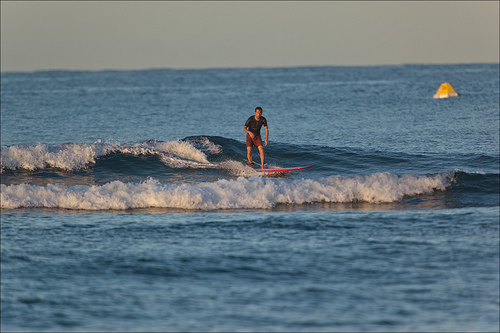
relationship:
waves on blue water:
[0, 135, 500, 174] [0, 63, 500, 331]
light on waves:
[177, 128, 367, 217] [203, 161, 474, 269]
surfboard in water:
[209, 141, 339, 197] [197, 197, 367, 284]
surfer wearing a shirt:
[241, 106, 268, 170] [248, 114, 267, 141]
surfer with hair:
[241, 106, 268, 170] [249, 102, 266, 117]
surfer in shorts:
[241, 106, 268, 170] [235, 131, 267, 171]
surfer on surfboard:
[241, 106, 268, 170] [230, 154, 282, 177]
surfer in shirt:
[241, 106, 268, 170] [246, 116, 270, 148]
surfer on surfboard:
[241, 106, 268, 170] [243, 152, 296, 177]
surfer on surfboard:
[241, 106, 268, 170] [239, 150, 270, 179]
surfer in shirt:
[241, 106, 268, 170] [241, 116, 273, 146]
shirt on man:
[246, 116, 268, 137] [241, 106, 268, 156]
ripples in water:
[0, 63, 500, 332] [7, 68, 497, 331]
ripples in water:
[175, 289, 306, 319] [7, 68, 497, 331]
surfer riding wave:
[241, 106, 268, 170] [0, 168, 500, 210]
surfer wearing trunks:
[241, 106, 268, 170] [244, 130, 261, 150]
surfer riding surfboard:
[241, 106, 268, 170] [233, 158, 313, 178]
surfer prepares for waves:
[241, 106, 268, 170] [9, 125, 489, 229]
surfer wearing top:
[241, 106, 268, 170] [241, 115, 271, 138]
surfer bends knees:
[241, 106, 268, 170] [239, 144, 268, 155]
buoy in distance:
[431, 66, 471, 106] [6, 57, 488, 148]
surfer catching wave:
[241, 106, 268, 170] [5, 127, 495, 230]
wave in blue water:
[0, 168, 500, 210] [0, 63, 500, 331]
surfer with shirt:
[234, 98, 284, 163] [243, 116, 266, 138]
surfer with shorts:
[241, 106, 268, 170] [238, 130, 273, 151]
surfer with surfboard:
[241, 106, 268, 170] [258, 163, 316, 174]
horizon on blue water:
[0, 62, 430, 102] [0, 63, 500, 331]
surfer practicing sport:
[241, 106, 268, 170] [241, 104, 308, 174]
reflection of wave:
[160, 174, 362, 211] [0, 168, 500, 210]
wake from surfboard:
[173, 155, 242, 175] [253, 163, 311, 174]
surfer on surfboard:
[241, 106, 268, 170] [258, 162, 314, 175]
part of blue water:
[334, 261, 414, 304] [16, 217, 482, 330]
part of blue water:
[64, 237, 128, 278] [16, 217, 482, 330]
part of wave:
[365, 171, 423, 203] [0, 168, 500, 210]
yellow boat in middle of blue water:
[430, 82, 456, 100] [0, 63, 500, 331]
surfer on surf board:
[241, 106, 268, 170] [256, 162, 316, 176]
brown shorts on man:
[245, 133, 261, 144] [242, 105, 268, 170]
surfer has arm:
[241, 106, 268, 170] [263, 121, 271, 147]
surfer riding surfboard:
[241, 106, 268, 170] [256, 161, 310, 174]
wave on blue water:
[0, 168, 500, 210] [0, 63, 500, 331]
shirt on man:
[244, 115, 267, 137] [242, 105, 268, 170]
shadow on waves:
[105, 135, 408, 185] [0, 135, 460, 223]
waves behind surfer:
[3, 136, 223, 166] [243, 109, 272, 167]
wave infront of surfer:
[0, 168, 500, 210] [241, 107, 271, 167]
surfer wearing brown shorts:
[241, 106, 268, 170] [245, 133, 261, 144]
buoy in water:
[431, 81, 458, 99] [7, 68, 497, 331]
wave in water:
[0, 168, 500, 210] [7, 68, 497, 331]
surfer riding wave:
[241, 106, 268, 170] [5, 135, 499, 178]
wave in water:
[5, 135, 499, 178] [7, 68, 497, 331]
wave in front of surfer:
[0, 168, 500, 210] [245, 107, 270, 170]